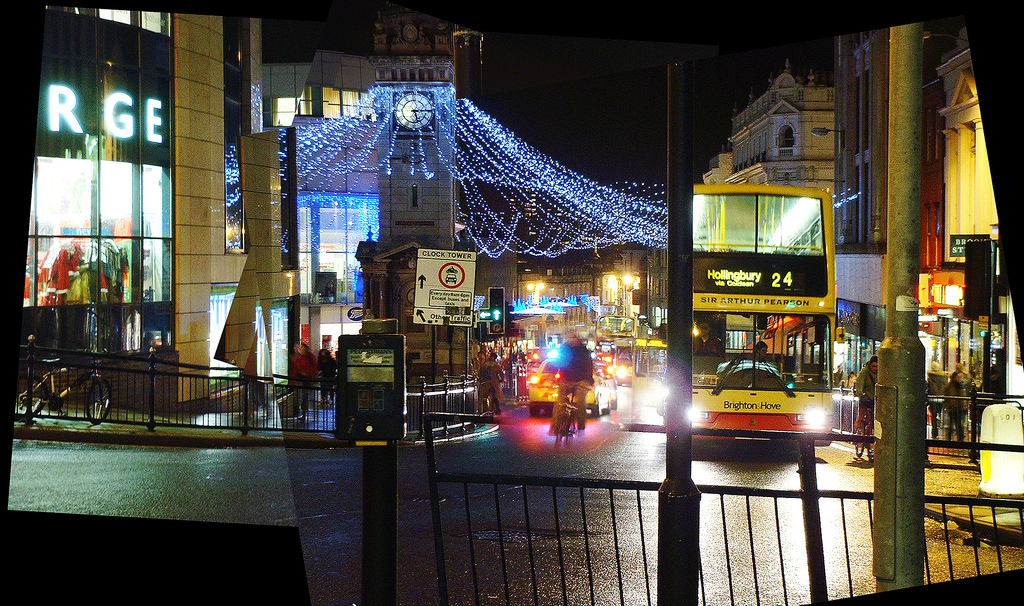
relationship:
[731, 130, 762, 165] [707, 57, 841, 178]
wall on side of a building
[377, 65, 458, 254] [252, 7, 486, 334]
wall on side of a building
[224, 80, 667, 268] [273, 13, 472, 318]
lights near building